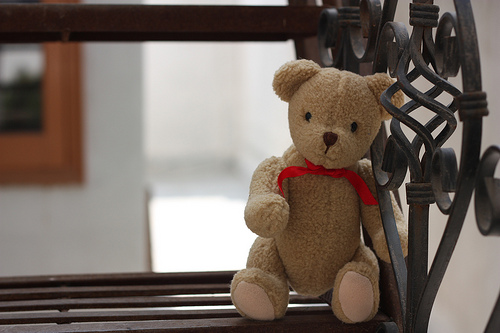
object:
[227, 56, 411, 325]
teddy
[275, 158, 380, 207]
ribbon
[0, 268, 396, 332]
bench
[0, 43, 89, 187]
picture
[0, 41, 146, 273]
wall